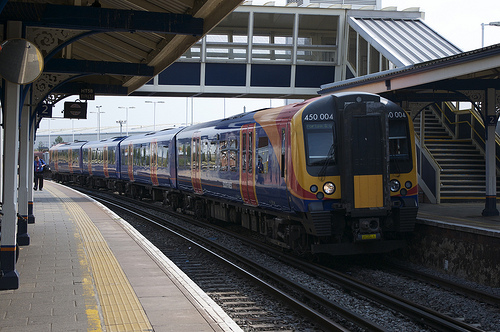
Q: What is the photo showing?
A: It is showing a train station.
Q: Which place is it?
A: It is a train station.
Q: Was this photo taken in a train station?
A: Yes, it was taken in a train station.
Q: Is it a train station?
A: Yes, it is a train station.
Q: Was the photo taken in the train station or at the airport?
A: It was taken at the train station.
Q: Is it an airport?
A: No, it is a train station.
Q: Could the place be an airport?
A: No, it is a train station.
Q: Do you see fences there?
A: No, there are no fences.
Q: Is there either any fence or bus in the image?
A: No, there are no fences or buses.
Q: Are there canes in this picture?
A: No, there are no canes.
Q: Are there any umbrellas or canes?
A: No, there are no canes or umbrellas.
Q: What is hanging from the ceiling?
A: The sign is hanging from the ceiling.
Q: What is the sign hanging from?
A: The sign is hanging from the ceiling.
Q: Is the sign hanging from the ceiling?
A: Yes, the sign is hanging from the ceiling.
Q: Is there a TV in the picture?
A: No, there are no televisions.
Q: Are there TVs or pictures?
A: No, there are no TVs or pictures.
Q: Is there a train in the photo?
A: Yes, there is a train.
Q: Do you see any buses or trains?
A: Yes, there is a train.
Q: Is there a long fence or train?
A: Yes, there is a long train.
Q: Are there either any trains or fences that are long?
A: Yes, the train is long.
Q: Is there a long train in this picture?
A: Yes, there is a long train.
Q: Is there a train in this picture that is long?
A: Yes, there is a train that is long.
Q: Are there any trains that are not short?
A: Yes, there is a long train.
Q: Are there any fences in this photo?
A: No, there are no fences.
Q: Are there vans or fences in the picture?
A: No, there are no fences or vans.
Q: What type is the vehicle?
A: The vehicle is a train.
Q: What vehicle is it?
A: The vehicle is a train.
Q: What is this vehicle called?
A: This is a train.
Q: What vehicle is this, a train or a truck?
A: This is a train.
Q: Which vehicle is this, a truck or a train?
A: This is a train.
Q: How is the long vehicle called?
A: The vehicle is a train.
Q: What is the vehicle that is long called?
A: The vehicle is a train.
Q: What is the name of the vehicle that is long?
A: The vehicle is a train.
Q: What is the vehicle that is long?
A: The vehicle is a train.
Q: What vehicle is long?
A: The vehicle is a train.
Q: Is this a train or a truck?
A: This is a train.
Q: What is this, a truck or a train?
A: This is a train.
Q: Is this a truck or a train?
A: This is a train.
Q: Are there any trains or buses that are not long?
A: No, there is a train but it is long.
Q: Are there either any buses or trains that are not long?
A: No, there is a train but it is long.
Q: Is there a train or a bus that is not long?
A: No, there is a train but it is long.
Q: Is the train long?
A: Yes, the train is long.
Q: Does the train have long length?
A: Yes, the train is long.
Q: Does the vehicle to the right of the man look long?
A: Yes, the train is long.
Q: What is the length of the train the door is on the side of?
A: The train is long.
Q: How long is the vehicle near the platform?
A: The train is long.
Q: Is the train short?
A: No, the train is long.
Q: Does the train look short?
A: No, the train is long.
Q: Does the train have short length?
A: No, the train is long.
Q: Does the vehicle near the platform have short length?
A: No, the train is long.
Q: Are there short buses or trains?
A: No, there is a train but it is long.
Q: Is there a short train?
A: No, there is a train but it is long.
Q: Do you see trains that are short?
A: No, there is a train but it is long.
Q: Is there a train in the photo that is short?
A: No, there is a train but it is long.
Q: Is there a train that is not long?
A: No, there is a train but it is long.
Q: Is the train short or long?
A: The train is long.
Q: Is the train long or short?
A: The train is long.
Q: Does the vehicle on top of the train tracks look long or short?
A: The train is long.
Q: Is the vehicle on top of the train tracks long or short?
A: The train is long.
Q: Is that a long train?
A: Yes, that is a long train.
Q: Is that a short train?
A: No, that is a long train.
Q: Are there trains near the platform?
A: Yes, there is a train near the platform.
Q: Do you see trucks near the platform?
A: No, there is a train near the platform.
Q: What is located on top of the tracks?
A: The train is on top of the tracks.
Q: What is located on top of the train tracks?
A: The train is on top of the tracks.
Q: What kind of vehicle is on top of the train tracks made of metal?
A: The vehicle is a train.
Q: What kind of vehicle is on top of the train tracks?
A: The vehicle is a train.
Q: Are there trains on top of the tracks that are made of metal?
A: Yes, there is a train on top of the tracks.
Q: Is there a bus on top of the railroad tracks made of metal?
A: No, there is a train on top of the tracks.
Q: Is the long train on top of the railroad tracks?
A: Yes, the train is on top of the railroad tracks.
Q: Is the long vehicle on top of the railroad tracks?
A: Yes, the train is on top of the railroad tracks.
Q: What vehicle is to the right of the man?
A: The vehicle is a train.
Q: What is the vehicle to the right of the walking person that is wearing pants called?
A: The vehicle is a train.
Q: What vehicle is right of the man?
A: The vehicle is a train.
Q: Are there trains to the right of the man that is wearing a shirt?
A: Yes, there is a train to the right of the man.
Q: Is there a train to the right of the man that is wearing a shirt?
A: Yes, there is a train to the right of the man.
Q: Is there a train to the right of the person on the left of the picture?
A: Yes, there is a train to the right of the man.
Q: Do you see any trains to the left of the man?
A: No, the train is to the right of the man.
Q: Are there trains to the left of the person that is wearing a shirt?
A: No, the train is to the right of the man.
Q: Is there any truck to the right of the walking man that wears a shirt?
A: No, there is a train to the right of the man.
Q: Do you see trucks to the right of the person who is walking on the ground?
A: No, there is a train to the right of the man.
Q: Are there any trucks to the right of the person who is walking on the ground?
A: No, there is a train to the right of the man.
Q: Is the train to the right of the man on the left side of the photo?
A: Yes, the train is to the right of the man.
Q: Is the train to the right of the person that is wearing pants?
A: Yes, the train is to the right of the man.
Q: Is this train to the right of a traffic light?
A: No, the train is to the right of the man.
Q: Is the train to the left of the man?
A: No, the train is to the right of the man.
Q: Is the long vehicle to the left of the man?
A: No, the train is to the right of the man.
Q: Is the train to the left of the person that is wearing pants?
A: No, the train is to the right of the man.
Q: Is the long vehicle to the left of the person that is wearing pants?
A: No, the train is to the right of the man.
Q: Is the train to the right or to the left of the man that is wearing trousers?
A: The train is to the right of the man.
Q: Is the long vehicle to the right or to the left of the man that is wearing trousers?
A: The train is to the right of the man.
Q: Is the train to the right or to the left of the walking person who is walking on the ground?
A: The train is to the right of the man.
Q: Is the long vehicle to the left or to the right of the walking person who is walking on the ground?
A: The train is to the right of the man.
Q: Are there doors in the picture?
A: Yes, there is a door.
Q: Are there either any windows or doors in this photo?
A: Yes, there is a door.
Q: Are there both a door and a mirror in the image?
A: Yes, there are both a door and a mirror.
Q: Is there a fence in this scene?
A: No, there are no fences.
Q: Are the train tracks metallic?
A: Yes, the train tracks are metallic.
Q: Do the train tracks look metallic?
A: Yes, the train tracks are metallic.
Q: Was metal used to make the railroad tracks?
A: Yes, the railroad tracks are made of metal.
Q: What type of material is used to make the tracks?
A: The tracks are made of metal.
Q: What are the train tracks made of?
A: The tracks are made of metal.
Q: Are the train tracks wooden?
A: No, the train tracks are metallic.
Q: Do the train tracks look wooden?
A: No, the train tracks are metallic.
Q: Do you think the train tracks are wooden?
A: No, the train tracks are metallic.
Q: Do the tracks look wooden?
A: No, the tracks are metallic.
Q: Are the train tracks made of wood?
A: No, the train tracks are made of metal.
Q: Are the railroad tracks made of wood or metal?
A: The railroad tracks are made of metal.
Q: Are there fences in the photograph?
A: No, there are no fences.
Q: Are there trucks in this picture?
A: No, there are no trucks.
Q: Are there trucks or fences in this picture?
A: No, there are no trucks or fences.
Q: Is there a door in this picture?
A: Yes, there is a door.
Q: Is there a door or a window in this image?
A: Yes, there is a door.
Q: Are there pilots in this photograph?
A: No, there are no pilots.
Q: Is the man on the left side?
A: Yes, the man is on the left of the image.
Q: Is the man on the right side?
A: No, the man is on the left of the image.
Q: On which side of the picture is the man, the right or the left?
A: The man is on the left of the image.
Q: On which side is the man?
A: The man is on the left of the image.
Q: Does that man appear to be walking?
A: Yes, the man is walking.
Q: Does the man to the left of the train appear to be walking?
A: Yes, the man is walking.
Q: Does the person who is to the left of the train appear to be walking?
A: Yes, the man is walking.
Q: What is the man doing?
A: The man is walking.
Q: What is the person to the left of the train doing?
A: The man is walking.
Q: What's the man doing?
A: The man is walking.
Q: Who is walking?
A: The man is walking.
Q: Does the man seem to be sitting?
A: No, the man is walking.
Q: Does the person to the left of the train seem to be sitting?
A: No, the man is walking.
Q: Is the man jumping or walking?
A: The man is walking.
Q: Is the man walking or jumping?
A: The man is walking.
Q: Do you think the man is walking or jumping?
A: The man is walking.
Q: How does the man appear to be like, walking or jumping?
A: The man is walking.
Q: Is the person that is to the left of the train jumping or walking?
A: The man is walking.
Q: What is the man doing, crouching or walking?
A: The man is walking.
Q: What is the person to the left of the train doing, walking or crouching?
A: The man is walking.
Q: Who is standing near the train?
A: The man is standing near the train.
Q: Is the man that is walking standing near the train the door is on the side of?
A: Yes, the man is standing near the train.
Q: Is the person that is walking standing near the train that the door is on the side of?
A: Yes, the man is standing near the train.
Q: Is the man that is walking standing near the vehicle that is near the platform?
A: Yes, the man is standing near the train.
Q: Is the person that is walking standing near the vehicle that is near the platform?
A: Yes, the man is standing near the train.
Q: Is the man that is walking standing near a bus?
A: No, the man is standing near the train.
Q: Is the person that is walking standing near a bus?
A: No, the man is standing near the train.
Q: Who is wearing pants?
A: The man is wearing pants.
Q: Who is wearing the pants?
A: The man is wearing pants.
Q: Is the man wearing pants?
A: Yes, the man is wearing pants.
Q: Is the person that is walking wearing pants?
A: Yes, the man is wearing pants.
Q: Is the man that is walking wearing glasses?
A: No, the man is wearing pants.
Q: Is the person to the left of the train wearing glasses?
A: No, the man is wearing pants.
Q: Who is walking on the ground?
A: The man is walking on the ground.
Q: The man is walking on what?
A: The man is walking on the ground.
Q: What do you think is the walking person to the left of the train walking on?
A: The man is walking on the ground.